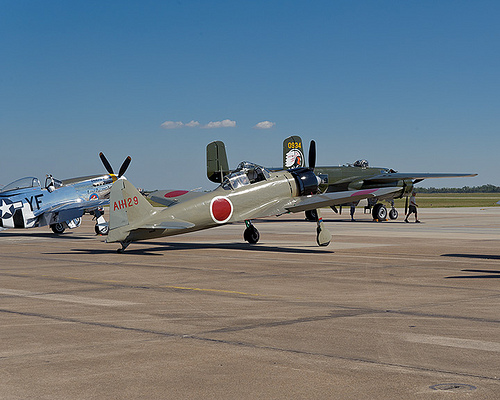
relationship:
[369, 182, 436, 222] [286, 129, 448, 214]
wheels of plane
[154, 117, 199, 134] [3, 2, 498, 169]
cloud in sky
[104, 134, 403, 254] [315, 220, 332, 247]
airplane has gear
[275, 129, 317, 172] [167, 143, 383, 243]
tail of plane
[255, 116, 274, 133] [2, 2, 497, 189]
cloud in sky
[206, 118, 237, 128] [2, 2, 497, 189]
cloud in sky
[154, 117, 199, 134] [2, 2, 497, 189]
cloud in sky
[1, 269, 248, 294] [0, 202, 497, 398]
stripe on tarmac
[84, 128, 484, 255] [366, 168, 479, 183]
airplane has airplane wing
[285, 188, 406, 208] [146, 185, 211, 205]
airplane wing has airplane wing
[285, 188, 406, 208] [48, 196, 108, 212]
airplane wing has airplane wing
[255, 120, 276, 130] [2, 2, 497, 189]
cloud in sky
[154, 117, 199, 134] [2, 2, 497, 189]
cloud are in sky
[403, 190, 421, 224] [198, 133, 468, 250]
man under plane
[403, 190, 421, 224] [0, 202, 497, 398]
man on tarmac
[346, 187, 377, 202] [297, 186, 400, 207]
stripe on wing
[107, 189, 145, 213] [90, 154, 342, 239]
lettering on plane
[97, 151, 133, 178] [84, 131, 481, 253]
propeller on plane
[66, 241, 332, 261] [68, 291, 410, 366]
shadow on tarmack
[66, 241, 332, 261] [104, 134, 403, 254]
shadow from airplane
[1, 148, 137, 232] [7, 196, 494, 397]
plane on lot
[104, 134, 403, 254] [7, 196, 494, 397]
airplane on lot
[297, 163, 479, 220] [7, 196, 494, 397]
plane on lot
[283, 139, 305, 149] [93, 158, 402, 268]
numbers are on plane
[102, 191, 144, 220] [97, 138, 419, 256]
numbers are on plane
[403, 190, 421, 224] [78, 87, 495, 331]
man walking by plane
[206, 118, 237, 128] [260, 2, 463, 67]
cloud in sky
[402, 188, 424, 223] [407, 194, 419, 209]
man dressed in shirt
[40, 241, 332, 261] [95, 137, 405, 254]
shadow on aircraft